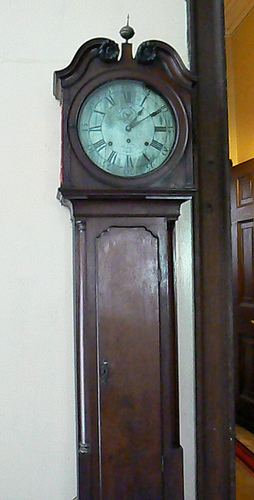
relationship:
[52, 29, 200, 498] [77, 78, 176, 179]
clock has clock face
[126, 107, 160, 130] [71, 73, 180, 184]
hands on clock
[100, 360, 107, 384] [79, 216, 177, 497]
handle on door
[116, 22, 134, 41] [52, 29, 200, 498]
decoration on clock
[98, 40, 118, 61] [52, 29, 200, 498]
decoration on clock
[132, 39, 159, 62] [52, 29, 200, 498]
rosettes on clock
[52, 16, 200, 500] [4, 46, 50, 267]
clock against wall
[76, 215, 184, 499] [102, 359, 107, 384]
door has handle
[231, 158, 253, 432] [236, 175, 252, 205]
door has bevels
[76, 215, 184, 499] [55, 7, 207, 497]
door on clock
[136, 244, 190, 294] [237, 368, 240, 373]
reflection of people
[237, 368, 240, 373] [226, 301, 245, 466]
people in mirror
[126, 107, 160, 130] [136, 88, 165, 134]
hands pointing 1:10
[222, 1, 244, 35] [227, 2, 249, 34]
trimming with border